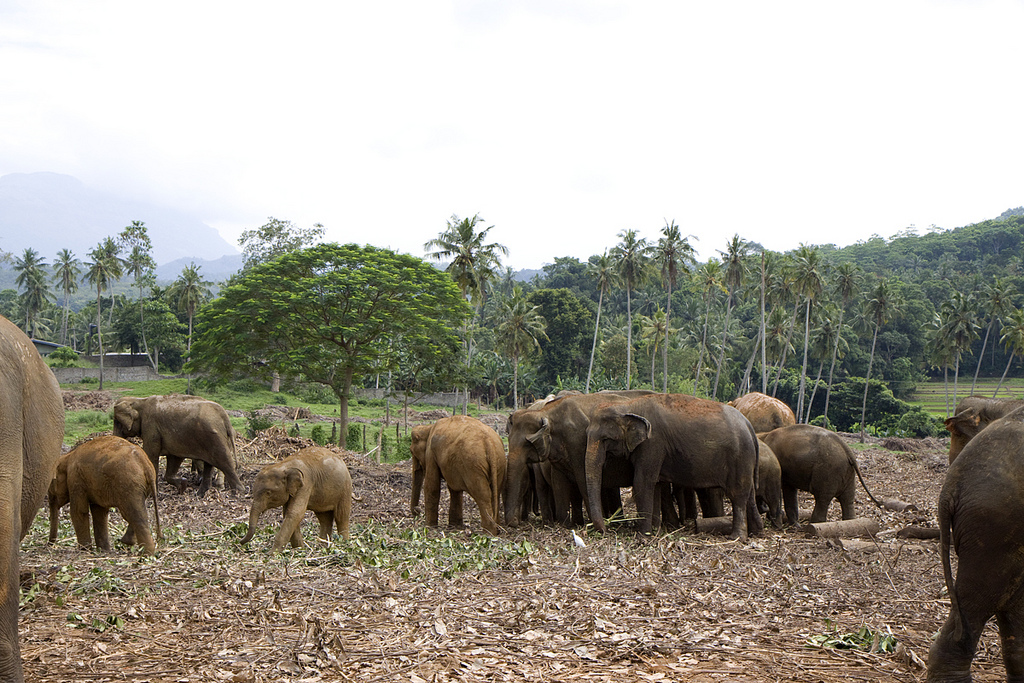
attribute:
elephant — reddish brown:
[405, 409, 512, 541]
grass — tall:
[362, 510, 542, 575]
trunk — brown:
[543, 376, 660, 532]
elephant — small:
[237, 430, 365, 560]